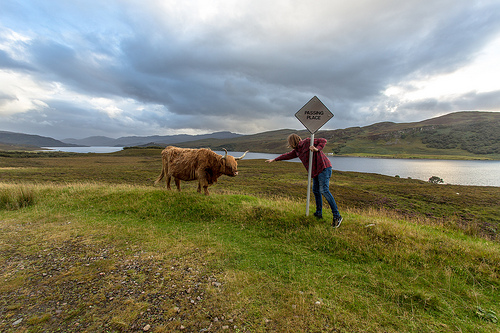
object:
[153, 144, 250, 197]
bull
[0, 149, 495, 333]
grass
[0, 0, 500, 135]
sky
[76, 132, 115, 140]
hill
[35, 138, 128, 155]
water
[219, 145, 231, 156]
horns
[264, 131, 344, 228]
woman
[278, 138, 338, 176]
sweater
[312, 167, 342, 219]
blue jeans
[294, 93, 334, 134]
sign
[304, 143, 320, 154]
left hand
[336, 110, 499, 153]
mountains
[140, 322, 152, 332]
pebbles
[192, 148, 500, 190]
lake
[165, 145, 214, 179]
fur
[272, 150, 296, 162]
arm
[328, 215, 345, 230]
shoes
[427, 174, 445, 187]
tree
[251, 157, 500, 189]
waterside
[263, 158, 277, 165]
hand